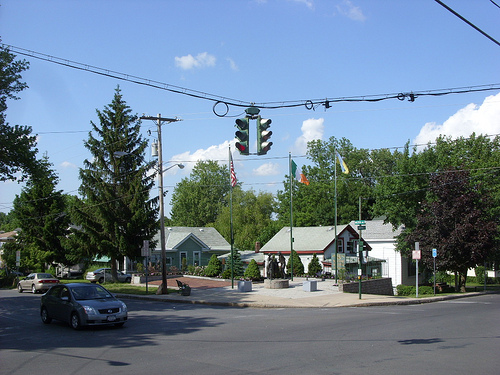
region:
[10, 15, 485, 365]
traffic light over residential intersection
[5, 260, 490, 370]
small car approaching intersection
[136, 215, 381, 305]
buildings with slanted roofs near corner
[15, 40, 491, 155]
traffic light hanging from black wires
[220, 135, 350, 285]
poles with different flags on top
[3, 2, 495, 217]
blue sky with white clouds over neighborhood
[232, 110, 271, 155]
A set of traffic lights on a wire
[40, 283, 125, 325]
A gray car on a road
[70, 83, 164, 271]
A tall pine tree near a road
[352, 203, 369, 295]
A pole with green signs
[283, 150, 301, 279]
A flag on a pole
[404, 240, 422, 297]
A sign on a gray pole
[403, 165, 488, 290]
A tree with dark leaves near a street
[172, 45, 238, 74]
A puffy cloud in the sky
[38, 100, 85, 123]
white clouds in blue sky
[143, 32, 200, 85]
white clouds in blue sky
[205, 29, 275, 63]
white clouds in blue sky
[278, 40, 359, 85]
white clouds in blue sky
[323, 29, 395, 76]
white clouds in blue sky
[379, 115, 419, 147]
white clouds in blue sky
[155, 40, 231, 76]
cloud in the sky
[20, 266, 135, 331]
car on the street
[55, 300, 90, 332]
tire of the car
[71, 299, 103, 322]
light on front of car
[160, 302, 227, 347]
shadow on the ground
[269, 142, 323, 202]
flag near the street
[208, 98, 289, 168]
lights above the ground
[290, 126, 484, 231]
trees near the street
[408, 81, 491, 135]
white clouds above the trees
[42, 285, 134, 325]
the car is silver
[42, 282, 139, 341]
car is at the light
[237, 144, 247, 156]
the light is red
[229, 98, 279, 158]
the traffic light is hanging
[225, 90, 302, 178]
traffic light on the wires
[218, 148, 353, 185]
falgs on the poles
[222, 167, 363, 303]
poles on the sidewalk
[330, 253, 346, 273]
the sign is green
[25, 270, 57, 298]
the car is parked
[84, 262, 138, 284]
car in the driveway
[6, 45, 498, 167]
a traffic light hanging by wires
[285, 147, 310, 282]
a flag on a flag pole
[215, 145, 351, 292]
three flags on a flag poles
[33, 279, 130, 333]
silver car on the road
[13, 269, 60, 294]
sand colored car on the road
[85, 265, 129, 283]
silver car parked in a driveway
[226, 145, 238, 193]
american flag on a flagpole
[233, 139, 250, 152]
glowing red light on a traffic signal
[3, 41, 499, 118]
wire used to hang traffic signals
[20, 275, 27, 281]
rear view mirror on a sand colored car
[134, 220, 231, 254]
roof on a green house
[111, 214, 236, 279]
green house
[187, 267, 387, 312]
a small plaza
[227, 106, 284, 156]
a pair of traffic lights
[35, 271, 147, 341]
car on the road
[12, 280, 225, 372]
shadow on the ground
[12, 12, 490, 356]
a bright and sunny day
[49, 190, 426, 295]
houses on the side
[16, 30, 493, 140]
traffic light cable set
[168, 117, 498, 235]
trees behind the houses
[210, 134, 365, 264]
a group of flags